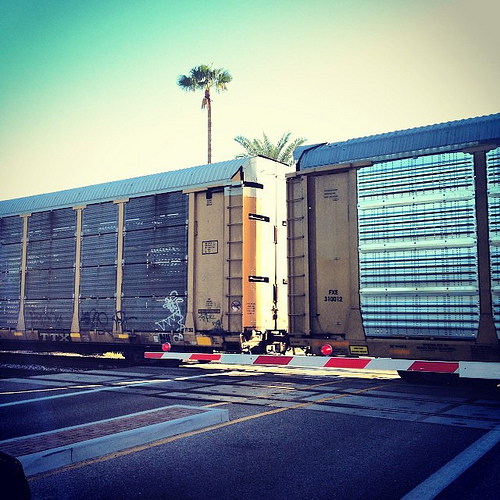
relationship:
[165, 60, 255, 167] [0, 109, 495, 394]
tree behind train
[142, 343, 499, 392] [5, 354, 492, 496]
crossing bar on street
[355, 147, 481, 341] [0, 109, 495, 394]
siding on train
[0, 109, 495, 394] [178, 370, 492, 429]
train on track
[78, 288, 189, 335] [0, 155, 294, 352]
grafitti on train car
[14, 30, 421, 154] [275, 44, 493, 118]
sky has cloud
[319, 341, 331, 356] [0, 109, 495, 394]
light on train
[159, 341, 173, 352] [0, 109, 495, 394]
light on train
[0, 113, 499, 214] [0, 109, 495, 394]
aluminum covering on train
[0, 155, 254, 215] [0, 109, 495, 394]
roof of train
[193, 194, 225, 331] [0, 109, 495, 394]
door of train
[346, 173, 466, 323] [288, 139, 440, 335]
panel on train